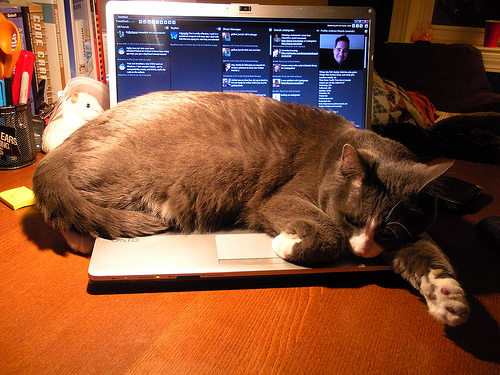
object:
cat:
[32, 89, 472, 326]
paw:
[414, 273, 470, 328]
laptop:
[88, 0, 395, 284]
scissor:
[0, 14, 24, 106]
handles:
[0, 12, 23, 78]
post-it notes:
[0, 183, 36, 210]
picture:
[318, 33, 367, 71]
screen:
[114, 13, 369, 129]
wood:
[0, 152, 497, 373]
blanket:
[371, 77, 441, 130]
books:
[28, 4, 50, 104]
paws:
[269, 227, 357, 268]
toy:
[41, 91, 103, 154]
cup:
[483, 18, 500, 50]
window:
[387, 3, 499, 44]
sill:
[472, 44, 498, 76]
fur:
[152, 112, 252, 184]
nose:
[349, 237, 378, 257]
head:
[318, 143, 457, 259]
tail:
[30, 151, 174, 239]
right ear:
[337, 143, 374, 190]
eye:
[340, 210, 369, 230]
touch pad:
[214, 232, 278, 261]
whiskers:
[380, 198, 412, 221]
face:
[332, 37, 350, 64]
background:
[0, 0, 499, 169]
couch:
[371, 43, 500, 154]